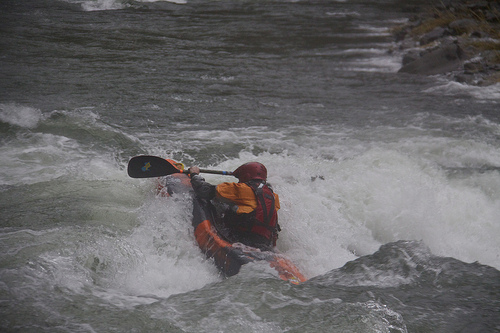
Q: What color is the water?
A: Gray.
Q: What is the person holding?
A: A paddle.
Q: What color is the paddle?
A: Black.